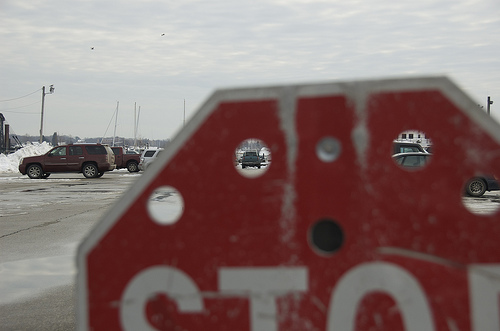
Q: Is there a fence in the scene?
A: No, there are no fences.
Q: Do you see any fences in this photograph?
A: No, there are no fences.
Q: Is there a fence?
A: No, there are no fences.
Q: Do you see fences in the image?
A: No, there are no fences.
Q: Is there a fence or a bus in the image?
A: No, there are no fences or buses.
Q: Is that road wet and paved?
A: Yes, the road is wet and paved.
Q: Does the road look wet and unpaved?
A: No, the road is wet but paved.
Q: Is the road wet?
A: Yes, the road is wet.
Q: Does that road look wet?
A: Yes, the road is wet.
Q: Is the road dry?
A: No, the road is wet.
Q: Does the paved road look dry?
A: No, the road is wet.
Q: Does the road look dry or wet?
A: The road is wet.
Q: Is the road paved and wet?
A: Yes, the road is paved and wet.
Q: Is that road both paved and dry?
A: No, the road is paved but wet.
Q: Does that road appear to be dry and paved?
A: No, the road is paved but wet.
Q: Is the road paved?
A: Yes, the road is paved.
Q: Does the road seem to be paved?
A: Yes, the road is paved.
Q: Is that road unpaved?
A: No, the road is paved.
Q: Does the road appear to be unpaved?
A: No, the road is paved.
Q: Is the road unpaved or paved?
A: The road is paved.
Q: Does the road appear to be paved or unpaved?
A: The road is paved.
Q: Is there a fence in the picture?
A: No, there are no fences.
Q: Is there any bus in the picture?
A: No, there are no buses.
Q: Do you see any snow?
A: Yes, there is snow.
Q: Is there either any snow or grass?
A: Yes, there is snow.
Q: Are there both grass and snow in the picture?
A: No, there is snow but no grass.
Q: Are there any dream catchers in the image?
A: No, there are no dream catchers.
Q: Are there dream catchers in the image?
A: No, there are no dream catchers.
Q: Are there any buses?
A: No, there are no buses.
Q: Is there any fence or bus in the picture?
A: No, there are no buses or fences.